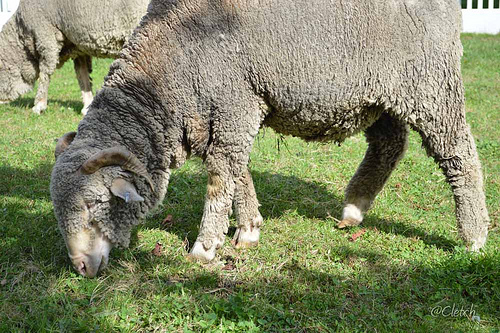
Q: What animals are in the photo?
A: Sheep.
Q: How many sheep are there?
A: Two.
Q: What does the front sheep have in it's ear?
A: A tag.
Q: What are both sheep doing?
A: Grazing.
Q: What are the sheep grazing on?
A: Grass.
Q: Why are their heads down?
A: To eat.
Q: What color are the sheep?
A: Gray.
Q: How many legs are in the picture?
A: Six.